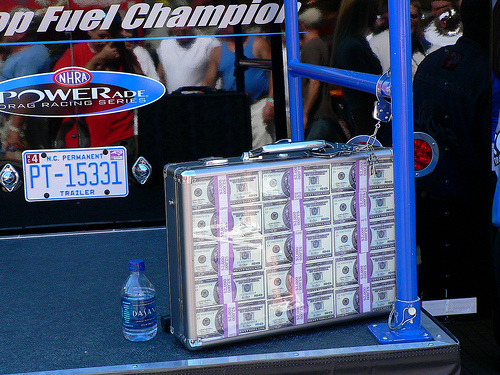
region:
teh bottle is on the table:
[103, 267, 165, 338]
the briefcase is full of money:
[165, 160, 404, 322]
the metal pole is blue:
[402, 154, 433, 346]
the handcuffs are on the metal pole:
[347, 57, 402, 139]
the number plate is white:
[17, 138, 146, 223]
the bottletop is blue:
[107, 241, 195, 291]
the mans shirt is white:
[152, 42, 229, 92]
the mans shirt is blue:
[213, 51, 273, 91]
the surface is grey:
[41, 281, 92, 346]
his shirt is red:
[51, 50, 144, 138]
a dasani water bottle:
[104, 245, 163, 350]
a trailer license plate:
[16, 144, 134, 208]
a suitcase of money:
[158, 145, 433, 357]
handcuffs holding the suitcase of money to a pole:
[326, 48, 434, 192]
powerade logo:
[0, 64, 169, 134]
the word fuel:
[37, 5, 122, 43]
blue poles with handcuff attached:
[266, 2, 431, 129]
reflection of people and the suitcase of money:
[155, 30, 282, 150]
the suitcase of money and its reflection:
[146, 72, 431, 364]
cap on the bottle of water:
[109, 253, 153, 279]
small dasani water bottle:
[121, 243, 161, 347]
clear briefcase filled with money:
[175, 73, 417, 356]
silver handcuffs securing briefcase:
[306, 67, 415, 175]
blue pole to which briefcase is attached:
[363, 12, 434, 354]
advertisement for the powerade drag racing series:
[4, 46, 184, 126]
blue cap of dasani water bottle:
[117, 253, 161, 285]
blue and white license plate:
[10, 130, 147, 218]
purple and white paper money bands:
[212, 202, 236, 247]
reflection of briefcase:
[130, 73, 266, 181]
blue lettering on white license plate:
[11, 137, 153, 211]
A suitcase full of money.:
[162, 151, 422, 346]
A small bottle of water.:
[110, 240, 160, 340]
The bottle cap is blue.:
[125, 255, 145, 270]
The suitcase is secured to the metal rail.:
[165, 56, 410, 341]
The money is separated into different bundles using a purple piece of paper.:
[186, 180, 271, 332]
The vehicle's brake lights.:
[350, 125, 455, 187]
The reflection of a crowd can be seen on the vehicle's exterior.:
[0, 10, 470, 115]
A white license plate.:
[20, 145, 130, 200]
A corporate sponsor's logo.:
[0, 60, 181, 136]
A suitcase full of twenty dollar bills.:
[190, 175, 411, 327]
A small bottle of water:
[113, 258, 159, 346]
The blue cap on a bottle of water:
[123, 255, 153, 275]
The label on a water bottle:
[117, 298, 157, 325]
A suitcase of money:
[164, 147, 409, 349]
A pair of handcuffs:
[310, 77, 401, 159]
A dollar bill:
[193, 175, 257, 207]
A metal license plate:
[22, 146, 131, 199]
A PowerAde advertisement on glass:
[2, 67, 167, 122]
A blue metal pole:
[391, 8, 423, 336]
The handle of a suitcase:
[243, 137, 340, 156]